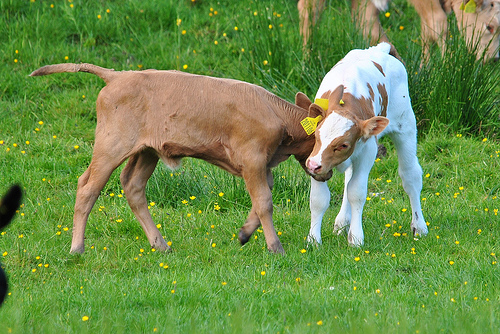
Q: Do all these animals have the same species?
A: Yes, all the animals are cows.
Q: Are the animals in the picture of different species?
A: No, all the animals are cows.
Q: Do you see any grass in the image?
A: Yes, there is grass.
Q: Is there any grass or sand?
A: Yes, there is grass.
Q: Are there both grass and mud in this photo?
A: No, there is grass but no mud.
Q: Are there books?
A: No, there are no books.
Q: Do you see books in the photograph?
A: No, there are no books.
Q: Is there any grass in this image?
A: Yes, there is grass.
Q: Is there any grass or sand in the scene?
A: Yes, there is grass.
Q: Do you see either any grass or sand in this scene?
A: Yes, there is grass.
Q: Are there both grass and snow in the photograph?
A: No, there is grass but no snow.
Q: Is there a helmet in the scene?
A: No, there are no helmets.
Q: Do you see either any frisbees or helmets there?
A: No, there are no helmets or frisbees.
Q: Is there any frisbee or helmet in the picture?
A: No, there are no helmets or frisbees.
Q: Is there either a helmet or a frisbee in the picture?
A: No, there are no helmets or frisbees.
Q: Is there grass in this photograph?
A: Yes, there is grass.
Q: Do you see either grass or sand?
A: Yes, there is grass.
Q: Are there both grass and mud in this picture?
A: No, there is grass but no mud.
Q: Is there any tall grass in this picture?
A: Yes, there is tall grass.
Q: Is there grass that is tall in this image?
A: Yes, there is tall grass.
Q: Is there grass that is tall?
A: Yes, there is grass that is tall.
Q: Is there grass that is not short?
A: Yes, there is tall grass.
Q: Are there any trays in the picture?
A: No, there are no trays.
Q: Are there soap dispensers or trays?
A: No, there are no trays or soap dispensers.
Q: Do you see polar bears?
A: No, there are no polar bears.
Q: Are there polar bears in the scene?
A: No, there are no polar bears.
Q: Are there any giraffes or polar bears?
A: No, there are no polar bears or giraffes.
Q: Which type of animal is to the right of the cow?
A: The animal is a calf.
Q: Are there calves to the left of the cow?
A: No, the calf is to the right of the cow.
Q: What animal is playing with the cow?
A: The calf is playing with the cow.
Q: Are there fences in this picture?
A: No, there are no fences.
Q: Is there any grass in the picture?
A: Yes, there is grass.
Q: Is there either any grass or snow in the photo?
A: Yes, there is grass.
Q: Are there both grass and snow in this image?
A: No, there is grass but no snow.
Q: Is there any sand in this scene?
A: No, there is no sand.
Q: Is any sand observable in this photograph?
A: No, there is no sand.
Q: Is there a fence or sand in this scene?
A: No, there are no sand or fences.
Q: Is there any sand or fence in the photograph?
A: No, there are no sand or fences.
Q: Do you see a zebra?
A: No, there are no zebras.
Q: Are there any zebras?
A: No, there are no zebras.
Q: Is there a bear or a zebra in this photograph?
A: No, there are no zebras or bears.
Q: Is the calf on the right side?
A: Yes, the calf is on the right of the image.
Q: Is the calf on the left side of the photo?
A: No, the calf is on the right of the image.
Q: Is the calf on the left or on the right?
A: The calf is on the right of the image.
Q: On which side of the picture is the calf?
A: The calf is on the right of the image.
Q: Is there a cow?
A: Yes, there is a cow.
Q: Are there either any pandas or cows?
A: Yes, there is a cow.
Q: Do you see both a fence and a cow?
A: No, there is a cow but no fences.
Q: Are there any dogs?
A: No, there are no dogs.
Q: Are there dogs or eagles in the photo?
A: No, there are no dogs or eagles.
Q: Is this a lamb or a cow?
A: This is a cow.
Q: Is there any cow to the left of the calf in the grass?
A: Yes, there is a cow to the left of the calf.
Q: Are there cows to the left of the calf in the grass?
A: Yes, there is a cow to the left of the calf.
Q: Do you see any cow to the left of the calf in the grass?
A: Yes, there is a cow to the left of the calf.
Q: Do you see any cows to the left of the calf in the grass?
A: Yes, there is a cow to the left of the calf.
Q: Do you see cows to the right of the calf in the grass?
A: No, the cow is to the left of the calf.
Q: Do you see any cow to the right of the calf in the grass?
A: No, the cow is to the left of the calf.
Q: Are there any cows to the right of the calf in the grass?
A: No, the cow is to the left of the calf.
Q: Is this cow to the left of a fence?
A: No, the cow is to the left of the calf.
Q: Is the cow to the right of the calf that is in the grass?
A: No, the cow is to the left of the calf.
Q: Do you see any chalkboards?
A: No, there are no chalkboards.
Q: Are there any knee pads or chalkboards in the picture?
A: No, there are no chalkboards or knee pads.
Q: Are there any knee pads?
A: No, there are no knee pads.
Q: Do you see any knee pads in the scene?
A: No, there are no knee pads.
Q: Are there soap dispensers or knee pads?
A: No, there are no knee pads or soap dispensers.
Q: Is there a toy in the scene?
A: No, there are no toys.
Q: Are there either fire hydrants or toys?
A: No, there are no toys or fire hydrants.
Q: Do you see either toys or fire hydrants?
A: No, there are no toys or fire hydrants.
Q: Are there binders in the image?
A: No, there are no binders.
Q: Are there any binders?
A: No, there are no binders.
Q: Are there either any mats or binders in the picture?
A: No, there are no binders or mats.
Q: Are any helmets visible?
A: No, there are no helmets.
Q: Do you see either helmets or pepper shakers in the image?
A: No, there are no helmets or pepper shakers.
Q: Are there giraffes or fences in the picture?
A: No, there are no fences or giraffes.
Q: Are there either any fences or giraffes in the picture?
A: No, there are no fences or giraffes.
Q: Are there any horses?
A: No, there are no horses.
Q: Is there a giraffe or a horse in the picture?
A: No, there are no horses or giraffes.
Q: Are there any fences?
A: No, there are no fences.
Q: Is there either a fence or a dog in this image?
A: No, there are no fences or dogs.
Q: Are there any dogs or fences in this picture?
A: No, there are no fences or dogs.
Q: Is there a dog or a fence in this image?
A: No, there are no fences or dogs.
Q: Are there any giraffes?
A: No, there are no giraffes.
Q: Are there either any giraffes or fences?
A: No, there are no giraffes or fences.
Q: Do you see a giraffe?
A: No, there are no giraffes.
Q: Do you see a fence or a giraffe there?
A: No, there are no giraffes or fences.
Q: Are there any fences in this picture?
A: No, there are no fences.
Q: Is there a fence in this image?
A: No, there are no fences.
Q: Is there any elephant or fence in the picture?
A: No, there are no fences or elephants.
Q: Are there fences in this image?
A: No, there are no fences.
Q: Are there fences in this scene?
A: No, there are no fences.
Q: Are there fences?
A: No, there are no fences.